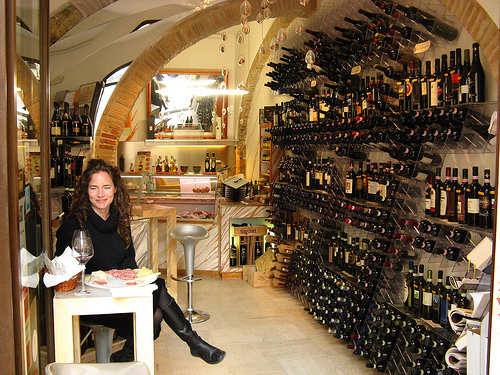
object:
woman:
[56, 160, 226, 365]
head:
[83, 164, 117, 210]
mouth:
[95, 198, 110, 203]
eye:
[88, 186, 99, 191]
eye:
[104, 186, 111, 190]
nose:
[96, 186, 104, 199]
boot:
[161, 297, 226, 364]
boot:
[110, 335, 134, 361]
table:
[53, 274, 156, 375]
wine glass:
[71, 229, 97, 298]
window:
[89, 59, 131, 146]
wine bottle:
[467, 43, 484, 102]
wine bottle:
[413, 16, 459, 42]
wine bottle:
[345, 161, 357, 200]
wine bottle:
[402, 260, 413, 312]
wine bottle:
[421, 271, 436, 321]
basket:
[41, 266, 80, 292]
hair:
[63, 159, 132, 251]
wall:
[234, 0, 498, 375]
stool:
[169, 223, 210, 324]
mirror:
[145, 69, 229, 140]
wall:
[50, 34, 235, 212]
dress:
[54, 207, 165, 336]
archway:
[92, 0, 318, 165]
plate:
[83, 269, 158, 290]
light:
[154, 87, 249, 98]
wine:
[50, 102, 63, 138]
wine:
[80, 105, 92, 135]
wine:
[61, 102, 72, 139]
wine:
[229, 236, 238, 268]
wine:
[478, 169, 493, 231]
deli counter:
[126, 173, 270, 275]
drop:
[236, 55, 245, 66]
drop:
[306, 49, 315, 65]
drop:
[239, 1, 252, 17]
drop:
[222, 31, 228, 42]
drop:
[276, 28, 287, 43]